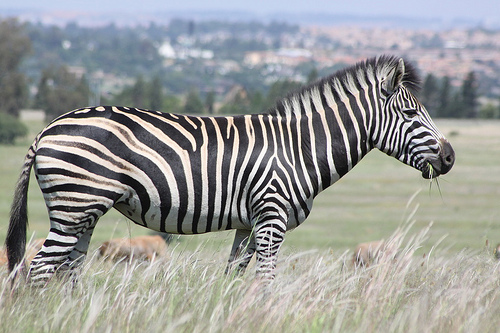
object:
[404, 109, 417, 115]
eye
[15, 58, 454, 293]
animal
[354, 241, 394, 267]
animal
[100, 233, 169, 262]
animal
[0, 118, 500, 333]
grass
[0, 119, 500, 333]
ground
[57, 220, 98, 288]
back leg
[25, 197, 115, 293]
back leg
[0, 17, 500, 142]
trees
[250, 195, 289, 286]
leg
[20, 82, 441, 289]
stripe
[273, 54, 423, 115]
hair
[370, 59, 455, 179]
head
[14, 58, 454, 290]
zebra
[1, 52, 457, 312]
zebra eating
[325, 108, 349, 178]
black stripe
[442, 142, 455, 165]
nose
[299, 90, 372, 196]
neck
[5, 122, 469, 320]
field